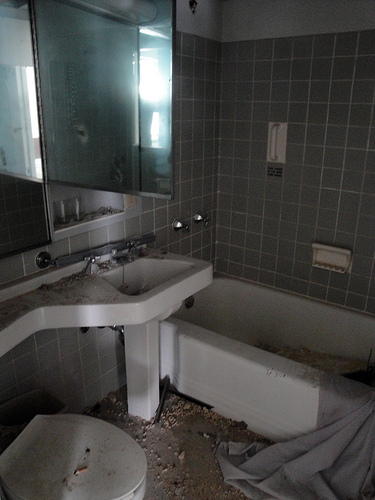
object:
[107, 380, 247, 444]
debris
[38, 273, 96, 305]
debris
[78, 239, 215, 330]
sink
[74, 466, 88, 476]
butt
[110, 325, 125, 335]
pipe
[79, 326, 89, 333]
pipe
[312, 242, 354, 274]
holder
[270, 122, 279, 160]
bar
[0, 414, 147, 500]
cover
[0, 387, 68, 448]
trash can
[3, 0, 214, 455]
wall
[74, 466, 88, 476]
cigarette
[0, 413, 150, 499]
lid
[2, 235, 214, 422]
sink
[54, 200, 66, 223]
glass cup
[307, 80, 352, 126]
ground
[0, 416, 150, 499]
seat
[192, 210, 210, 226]
knob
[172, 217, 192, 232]
knob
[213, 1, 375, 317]
shower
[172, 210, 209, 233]
handles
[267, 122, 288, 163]
grip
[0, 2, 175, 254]
mirror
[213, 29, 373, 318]
wall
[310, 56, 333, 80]
tile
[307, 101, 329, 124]
tile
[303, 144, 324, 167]
tile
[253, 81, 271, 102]
tile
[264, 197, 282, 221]
tile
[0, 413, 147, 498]
toilet seat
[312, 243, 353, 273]
soap dish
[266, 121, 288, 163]
handle bar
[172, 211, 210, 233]
water fixtures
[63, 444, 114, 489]
dirt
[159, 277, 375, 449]
tub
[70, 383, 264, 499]
floor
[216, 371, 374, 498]
cloth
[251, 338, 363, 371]
dirt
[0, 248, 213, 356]
counter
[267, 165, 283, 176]
lettering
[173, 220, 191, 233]
handle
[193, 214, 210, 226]
handle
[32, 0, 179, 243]
cabinet